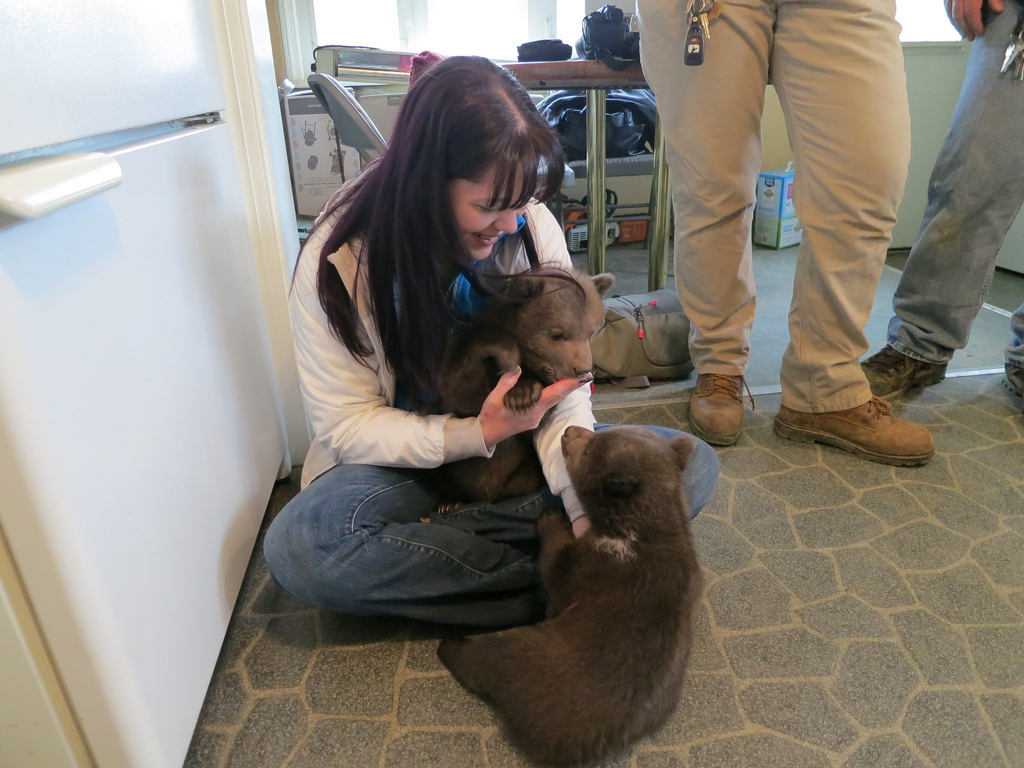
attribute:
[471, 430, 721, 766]
bear — brown 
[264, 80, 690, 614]
sweater — white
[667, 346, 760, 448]
boot — brown